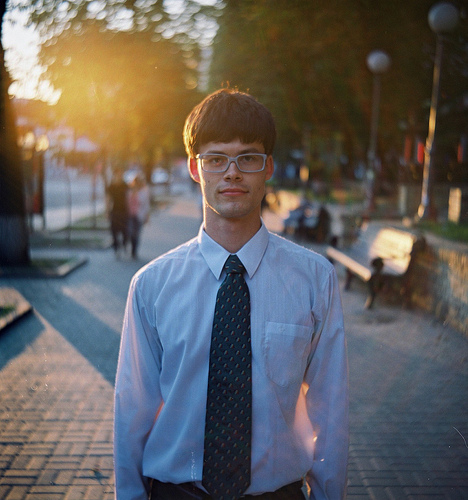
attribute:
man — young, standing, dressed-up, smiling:
[114, 86, 354, 500]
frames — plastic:
[195, 150, 270, 174]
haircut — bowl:
[181, 91, 280, 154]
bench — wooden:
[330, 226, 422, 313]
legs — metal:
[327, 253, 415, 313]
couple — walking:
[105, 170, 154, 258]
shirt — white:
[106, 228, 351, 454]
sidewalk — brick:
[21, 263, 116, 488]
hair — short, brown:
[184, 91, 279, 149]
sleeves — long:
[116, 275, 160, 486]